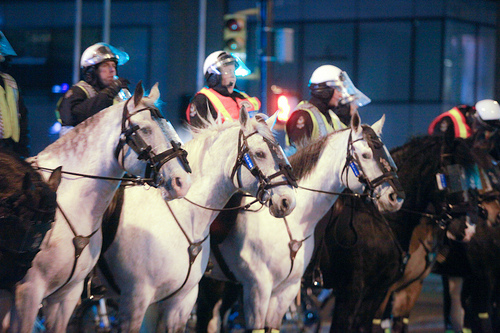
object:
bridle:
[231, 130, 299, 203]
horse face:
[242, 120, 296, 218]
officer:
[55, 42, 130, 127]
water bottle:
[112, 75, 132, 101]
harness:
[165, 202, 211, 301]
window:
[302, 19, 355, 101]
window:
[358, 22, 412, 102]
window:
[415, 19, 443, 103]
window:
[442, 19, 478, 103]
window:
[477, 25, 498, 101]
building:
[3, 0, 498, 142]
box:
[260, 27, 294, 64]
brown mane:
[286, 127, 348, 179]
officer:
[185, 50, 261, 139]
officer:
[0, 32, 32, 158]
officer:
[428, 98, 500, 138]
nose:
[279, 196, 296, 210]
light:
[226, 19, 243, 32]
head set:
[82, 66, 98, 85]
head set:
[310, 83, 333, 101]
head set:
[206, 72, 221, 88]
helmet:
[203, 50, 239, 75]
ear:
[370, 113, 385, 134]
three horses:
[0, 78, 408, 333]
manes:
[179, 113, 275, 158]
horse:
[202, 112, 406, 333]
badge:
[296, 116, 305, 129]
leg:
[242, 282, 272, 332]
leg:
[157, 285, 199, 332]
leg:
[41, 282, 83, 332]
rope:
[184, 197, 259, 212]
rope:
[166, 203, 193, 242]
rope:
[56, 204, 78, 236]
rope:
[284, 218, 294, 241]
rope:
[301, 184, 369, 198]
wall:
[426, 54, 447, 99]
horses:
[0, 81, 195, 333]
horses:
[196, 120, 489, 333]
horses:
[0, 152, 61, 286]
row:
[4, 77, 500, 333]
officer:
[285, 64, 371, 153]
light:
[232, 55, 248, 77]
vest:
[186, 86, 262, 133]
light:
[227, 39, 242, 52]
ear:
[350, 111, 361, 133]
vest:
[285, 100, 349, 149]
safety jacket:
[429, 105, 473, 141]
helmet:
[80, 44, 118, 69]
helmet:
[474, 99, 499, 121]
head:
[309, 64, 346, 108]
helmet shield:
[326, 71, 371, 107]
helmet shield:
[211, 52, 251, 77]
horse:
[88, 105, 298, 333]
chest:
[239, 215, 313, 287]